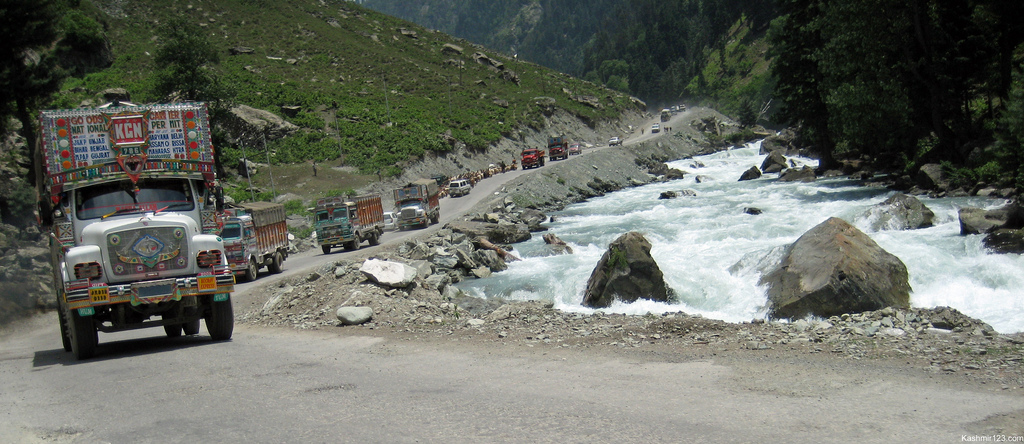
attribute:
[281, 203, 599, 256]
river — raging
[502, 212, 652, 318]
river — raging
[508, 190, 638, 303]
river — raging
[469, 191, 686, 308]
river — raging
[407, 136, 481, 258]
river — raging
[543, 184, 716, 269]
river — raging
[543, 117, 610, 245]
river — raging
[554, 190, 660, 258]
river — raging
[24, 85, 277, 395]
truck — big, colorful, large, white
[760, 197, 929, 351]
boulder — brown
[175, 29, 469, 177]
hill — lush, green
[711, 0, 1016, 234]
trees — lush, green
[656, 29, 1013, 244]
trees — leafy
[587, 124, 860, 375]
river — choppy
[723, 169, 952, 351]
rocks — large, gray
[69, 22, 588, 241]
hills — green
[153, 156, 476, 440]
road — curve, gray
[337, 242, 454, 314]
rock — white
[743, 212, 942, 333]
boulder — Large, stone 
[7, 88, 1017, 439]
mountain road — Winding 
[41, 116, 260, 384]
truck — Multicolored , decorated 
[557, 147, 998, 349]
caps — White 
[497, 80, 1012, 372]
water — flowing 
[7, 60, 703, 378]
traffic — Line 